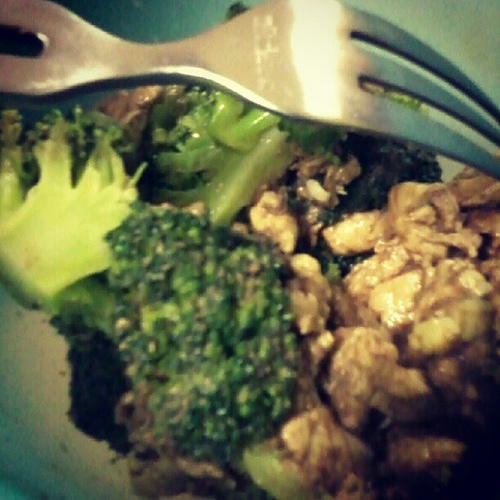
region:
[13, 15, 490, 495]
close up image of food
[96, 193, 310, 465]
broccoli floret in bowl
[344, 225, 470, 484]
chicken in a bowl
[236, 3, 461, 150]
silver fork in bowl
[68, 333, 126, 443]
shadow on the bowl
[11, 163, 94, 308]
stalk of a piece of broccoli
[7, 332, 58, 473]
white bowl with food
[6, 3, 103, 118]
handle of a fork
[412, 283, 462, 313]
sauce on chicken pieces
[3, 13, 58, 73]
design on a fork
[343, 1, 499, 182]
Prongs of a fork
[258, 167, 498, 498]
Many pieces of meat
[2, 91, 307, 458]
Cooked pieces of green vegetable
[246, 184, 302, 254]
One piece of meat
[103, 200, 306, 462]
Very green piece of vegetable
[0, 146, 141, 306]
Cut stalk of vegetable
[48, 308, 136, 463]
Shadow of a vegetable piece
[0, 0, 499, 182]
Fork on top of food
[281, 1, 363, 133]
Bright reflection on metal surface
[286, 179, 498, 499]
Shiny brown color of oily meat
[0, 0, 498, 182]
a silver plated fork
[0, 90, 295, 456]
these are green vegetables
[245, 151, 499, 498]
this is some meat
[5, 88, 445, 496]
a platter of broccoli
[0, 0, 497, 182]
there is a fork in the food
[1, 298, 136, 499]
this is a platter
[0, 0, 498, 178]
this is a big fork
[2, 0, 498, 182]
this fork is upside down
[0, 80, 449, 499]
these are green steamed broccoli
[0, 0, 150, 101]
this a handle of a fork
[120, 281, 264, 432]
chopped broccoli near fork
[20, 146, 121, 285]
chopped broccoli near fork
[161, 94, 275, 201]
chopped broccoli near fork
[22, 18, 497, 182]
silver fork over broccoli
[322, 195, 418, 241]
brown pieces of meat on right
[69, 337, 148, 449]
shadow of broccoli on plate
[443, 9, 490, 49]
white wall in background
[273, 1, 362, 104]
light shining off fork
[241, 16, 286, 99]
small writing in fork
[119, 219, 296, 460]
green head of broccoli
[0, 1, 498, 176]
fork on plate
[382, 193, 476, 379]
meat in dish with sauce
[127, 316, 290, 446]
broccoli florets in food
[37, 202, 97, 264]
light green broccoli floret heart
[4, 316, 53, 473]
white dish under food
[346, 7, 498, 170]
fork has three prongs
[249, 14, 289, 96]
engraving on back of fork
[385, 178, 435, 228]
cooked onion in food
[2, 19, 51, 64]
hole cut out of fork handle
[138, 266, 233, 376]
dark green head of broccoli floret